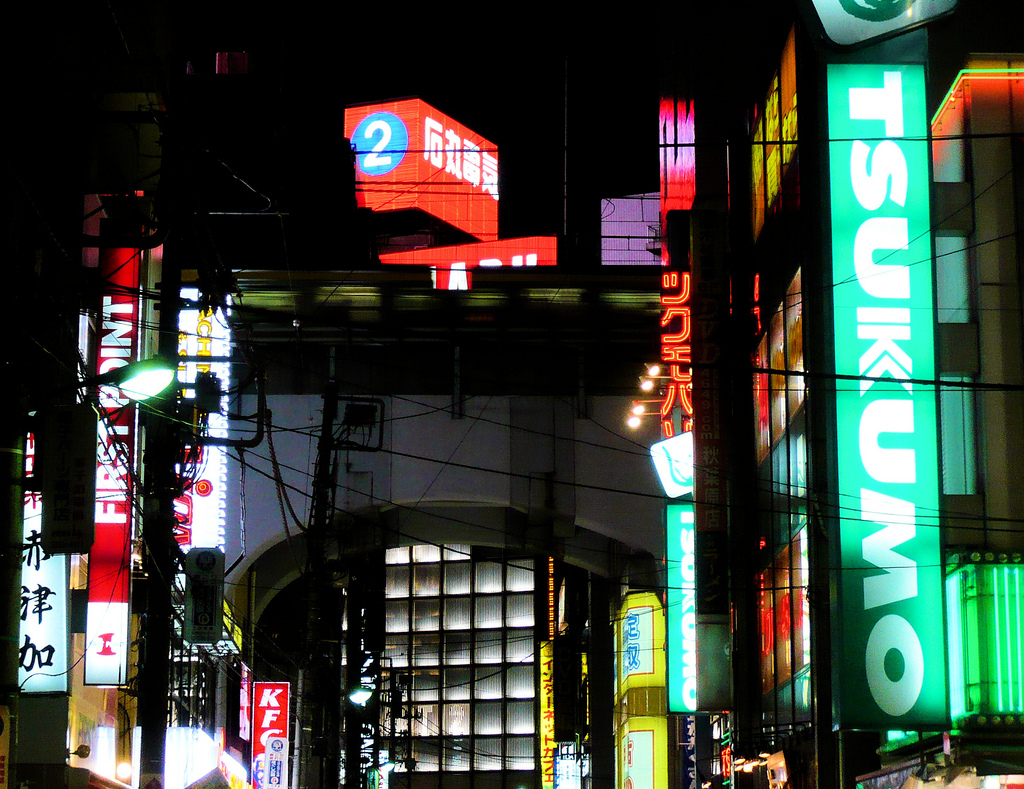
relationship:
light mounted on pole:
[113, 341, 189, 418] [135, 396, 175, 785]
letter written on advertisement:
[831, 54, 927, 138] [824, 55, 952, 727]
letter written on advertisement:
[845, 132, 910, 210] [824, 55, 952, 727]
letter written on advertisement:
[854, 394, 919, 485] [824, 55, 952, 727]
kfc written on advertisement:
[250, 681, 292, 787] [247, 673, 293, 784]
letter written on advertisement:
[20, 526, 55, 570] [16, 420, 73, 693]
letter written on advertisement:
[29, 573, 53, 623] [16, 420, 73, 693]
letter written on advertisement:
[16, 582, 30, 619] [16, 420, 73, 693]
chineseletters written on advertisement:
[20, 634, 54, 671] [16, 420, 73, 693]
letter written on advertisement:
[418, 113, 442, 168] [340, 96, 503, 243]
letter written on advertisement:
[459, 134, 481, 184] [340, 96, 503, 243]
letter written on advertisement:
[443, 128, 459, 174] [340, 96, 503, 243]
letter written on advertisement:
[482, 148, 502, 196] [340, 96, 503, 243]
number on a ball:
[364, 120, 391, 166] [350, 113, 409, 175]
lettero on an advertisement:
[866, 614, 928, 716] [848, 10, 948, 752]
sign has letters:
[822, 59, 928, 718] [824, 62, 959, 771]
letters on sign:
[806, 83, 979, 775] [830, 59, 940, 726]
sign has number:
[830, 59, 940, 726] [776, 47, 973, 784]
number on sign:
[791, 81, 960, 712] [830, 59, 940, 726]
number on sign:
[335, 105, 405, 188] [830, 59, 940, 726]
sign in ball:
[830, 59, 940, 726] [312, 105, 429, 203]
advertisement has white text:
[252, 681, 289, 784] [201, 662, 327, 753]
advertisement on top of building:
[252, 681, 289, 784] [286, 83, 611, 312]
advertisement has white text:
[252, 681, 289, 784] [402, 105, 550, 214]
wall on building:
[14, 398, 387, 661] [11, 200, 383, 754]